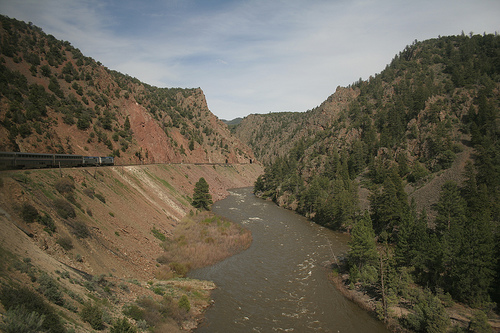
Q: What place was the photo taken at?
A: It was taken at the forest.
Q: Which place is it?
A: It is a forest.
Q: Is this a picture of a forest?
A: Yes, it is showing a forest.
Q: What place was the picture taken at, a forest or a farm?
A: It was taken at a forest.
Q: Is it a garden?
A: No, it is a forest.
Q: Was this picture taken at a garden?
A: No, the picture was taken in a forest.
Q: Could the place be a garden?
A: No, it is a forest.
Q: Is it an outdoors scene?
A: Yes, it is outdoors.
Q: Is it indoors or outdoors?
A: It is outdoors.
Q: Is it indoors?
A: No, it is outdoors.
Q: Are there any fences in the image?
A: No, there are no fences.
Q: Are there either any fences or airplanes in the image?
A: No, there are no fences or airplanes.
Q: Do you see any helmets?
A: No, there are no helmets.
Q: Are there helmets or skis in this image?
A: No, there are no helmets or skis.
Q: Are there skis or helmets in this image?
A: No, there are no helmets or skis.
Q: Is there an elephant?
A: No, there are no elephants.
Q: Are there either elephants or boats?
A: No, there are no elephants or boats.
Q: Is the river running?
A: Yes, the river is running.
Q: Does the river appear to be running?
A: Yes, the river is running.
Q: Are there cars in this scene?
A: No, there are no cars.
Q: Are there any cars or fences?
A: No, there are no cars or fences.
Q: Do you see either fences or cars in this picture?
A: No, there are no cars or fences.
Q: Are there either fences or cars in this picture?
A: No, there are no cars or fences.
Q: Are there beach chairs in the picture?
A: No, there are no beach chairs.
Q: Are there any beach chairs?
A: No, there are no beach chairs.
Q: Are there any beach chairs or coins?
A: No, there are no beach chairs or coins.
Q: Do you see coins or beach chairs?
A: No, there are no beach chairs or coins.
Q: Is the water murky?
A: Yes, the water is murky.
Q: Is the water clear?
A: No, the water is murky.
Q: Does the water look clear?
A: No, the water is murky.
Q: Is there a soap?
A: No, there are no soaps.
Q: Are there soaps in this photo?
A: No, there are no soaps.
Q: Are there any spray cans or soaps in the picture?
A: No, there are no soaps or spray cans.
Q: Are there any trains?
A: Yes, there is a train.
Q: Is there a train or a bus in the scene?
A: Yes, there is a train.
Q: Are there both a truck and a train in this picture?
A: No, there is a train but no trucks.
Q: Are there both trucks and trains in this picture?
A: No, there is a train but no trucks.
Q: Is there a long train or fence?
A: Yes, there is a long train.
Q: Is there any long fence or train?
A: Yes, there is a long train.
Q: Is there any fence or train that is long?
A: Yes, the train is long.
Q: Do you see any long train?
A: Yes, there is a long train.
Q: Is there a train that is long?
A: Yes, there is a train that is long.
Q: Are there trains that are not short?
A: Yes, there is a long train.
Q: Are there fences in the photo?
A: No, there are no fences.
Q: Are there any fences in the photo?
A: No, there are no fences.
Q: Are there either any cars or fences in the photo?
A: No, there are no fences or cars.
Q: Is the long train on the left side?
A: Yes, the train is on the left of the image.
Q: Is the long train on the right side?
A: No, the train is on the left of the image.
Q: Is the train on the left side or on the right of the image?
A: The train is on the left of the image.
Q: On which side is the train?
A: The train is on the left of the image.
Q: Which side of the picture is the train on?
A: The train is on the left of the image.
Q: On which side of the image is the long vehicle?
A: The train is on the left of the image.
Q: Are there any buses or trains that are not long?
A: No, there is a train but it is long.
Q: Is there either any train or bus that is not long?
A: No, there is a train but it is long.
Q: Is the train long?
A: Yes, the train is long.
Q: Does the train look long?
A: Yes, the train is long.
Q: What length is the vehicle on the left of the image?
A: The train is long.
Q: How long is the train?
A: The train is long.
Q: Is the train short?
A: No, the train is long.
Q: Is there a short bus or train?
A: No, there is a train but it is long.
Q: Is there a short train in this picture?
A: No, there is a train but it is long.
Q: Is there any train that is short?
A: No, there is a train but it is long.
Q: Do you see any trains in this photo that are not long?
A: No, there is a train but it is long.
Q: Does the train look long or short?
A: The train is long.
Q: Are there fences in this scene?
A: No, there are no fences.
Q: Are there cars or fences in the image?
A: No, there are no fences or cars.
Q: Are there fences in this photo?
A: No, there are no fences.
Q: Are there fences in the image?
A: No, there are no fences.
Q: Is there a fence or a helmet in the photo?
A: No, there are no fences or helmets.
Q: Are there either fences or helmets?
A: No, there are no fences or helmets.